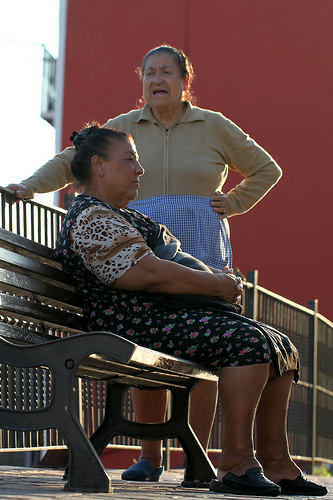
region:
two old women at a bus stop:
[90, 13, 331, 498]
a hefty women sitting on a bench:
[56, 119, 320, 498]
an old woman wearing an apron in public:
[117, 41, 281, 250]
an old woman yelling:
[137, 40, 296, 264]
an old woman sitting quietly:
[73, 121, 323, 495]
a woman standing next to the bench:
[72, 5, 330, 303]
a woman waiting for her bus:
[67, 128, 330, 499]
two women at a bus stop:
[0, 35, 324, 497]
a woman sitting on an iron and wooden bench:
[1, 122, 331, 498]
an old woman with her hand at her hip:
[108, 28, 294, 275]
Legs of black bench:
[1, 353, 226, 494]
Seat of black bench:
[0, 325, 224, 404]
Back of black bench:
[0, 217, 96, 357]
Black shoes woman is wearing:
[203, 464, 326, 496]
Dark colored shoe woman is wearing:
[112, 455, 168, 484]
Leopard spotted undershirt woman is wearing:
[59, 200, 155, 287]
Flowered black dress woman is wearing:
[48, 194, 310, 377]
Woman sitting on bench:
[50, 116, 328, 498]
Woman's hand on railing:
[2, 180, 34, 206]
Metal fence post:
[303, 292, 321, 459]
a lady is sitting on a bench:
[1, 122, 332, 498]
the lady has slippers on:
[210, 461, 327, 496]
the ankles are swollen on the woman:
[213, 435, 306, 487]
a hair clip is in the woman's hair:
[63, 127, 86, 147]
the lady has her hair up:
[63, 119, 147, 207]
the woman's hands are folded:
[210, 253, 244, 309]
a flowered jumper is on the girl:
[55, 192, 300, 374]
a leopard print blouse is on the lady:
[66, 201, 152, 284]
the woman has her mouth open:
[125, 43, 193, 111]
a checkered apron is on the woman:
[129, 192, 233, 275]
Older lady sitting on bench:
[56, 114, 326, 495]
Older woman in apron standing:
[2, 37, 286, 484]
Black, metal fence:
[1, 186, 332, 464]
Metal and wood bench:
[0, 224, 228, 494]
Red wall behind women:
[60, 1, 332, 476]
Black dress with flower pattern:
[45, 194, 308, 386]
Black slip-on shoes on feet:
[203, 469, 330, 497]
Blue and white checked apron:
[126, 193, 233, 275]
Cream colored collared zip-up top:
[7, 101, 292, 217]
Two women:
[7, 38, 330, 497]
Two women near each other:
[11, 36, 300, 495]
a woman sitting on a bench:
[62, 113, 303, 498]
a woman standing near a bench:
[77, 42, 258, 466]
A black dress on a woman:
[67, 201, 281, 386]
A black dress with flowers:
[56, 188, 313, 382]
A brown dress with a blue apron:
[91, 95, 276, 252]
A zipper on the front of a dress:
[156, 122, 173, 202]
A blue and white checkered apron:
[153, 193, 246, 271]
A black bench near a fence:
[4, 225, 208, 499]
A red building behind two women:
[56, 10, 326, 312]